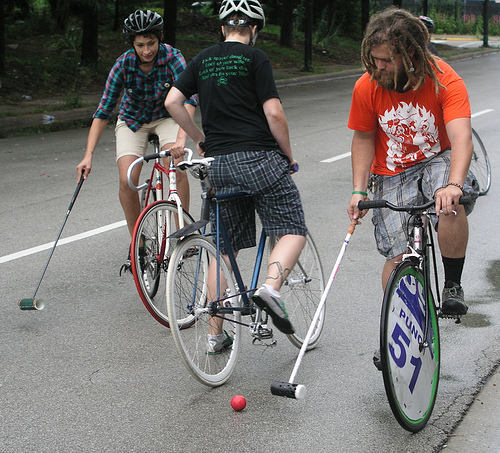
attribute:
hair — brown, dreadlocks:
[392, 40, 421, 66]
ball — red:
[229, 387, 249, 413]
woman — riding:
[91, 21, 185, 176]